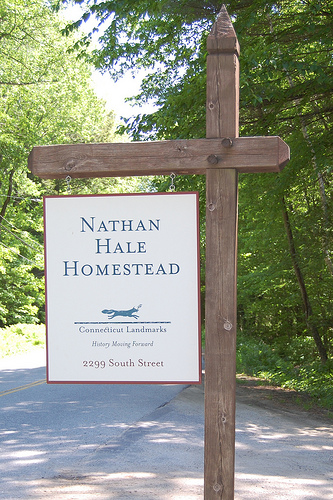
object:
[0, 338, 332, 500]
road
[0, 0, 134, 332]
trees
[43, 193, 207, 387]
sign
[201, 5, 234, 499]
post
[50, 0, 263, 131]
sky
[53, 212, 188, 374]
writing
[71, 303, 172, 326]
logo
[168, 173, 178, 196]
chains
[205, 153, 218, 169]
bolts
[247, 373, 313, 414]
dirt